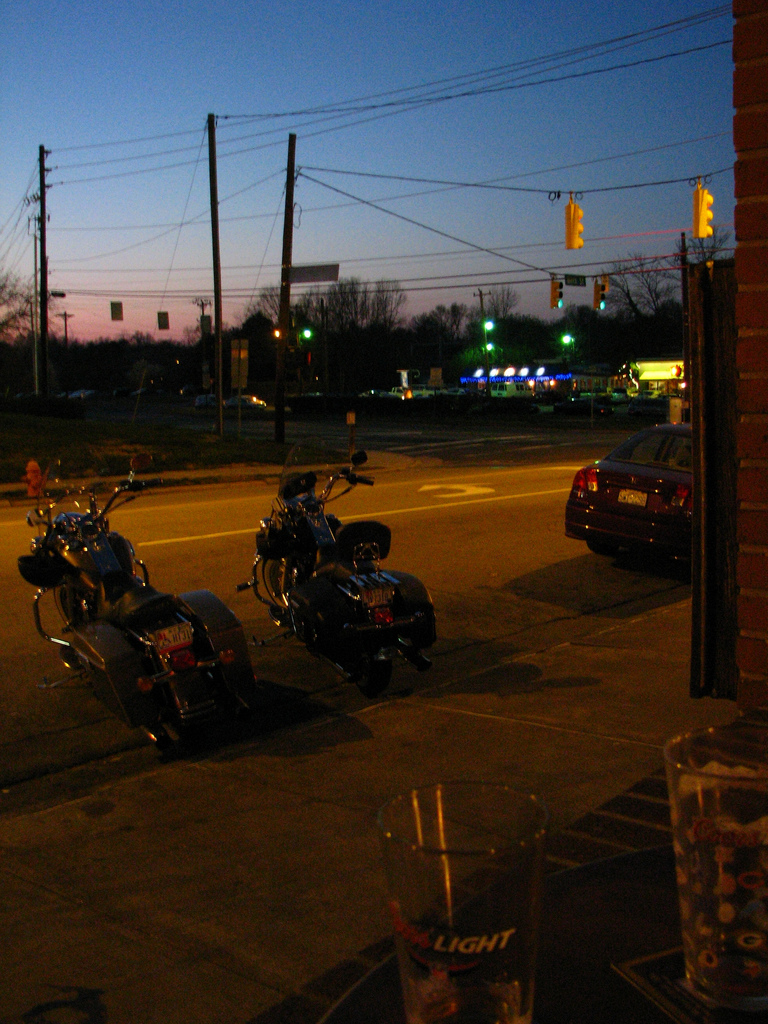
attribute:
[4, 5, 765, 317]
wires — suspended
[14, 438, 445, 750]
motorcycles — parked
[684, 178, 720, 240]
traffic light — hanging